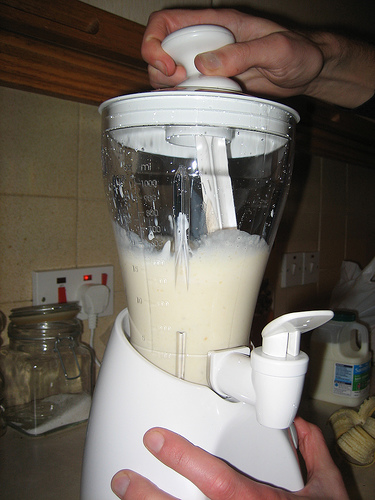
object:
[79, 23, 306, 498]
blender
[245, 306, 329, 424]
spout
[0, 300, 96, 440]
canister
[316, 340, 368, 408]
milk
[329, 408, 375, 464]
banana peel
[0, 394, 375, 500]
counter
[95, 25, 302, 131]
top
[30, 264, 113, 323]
wall outlet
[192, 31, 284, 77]
fingers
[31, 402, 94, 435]
powder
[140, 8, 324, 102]
hand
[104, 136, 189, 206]
splatters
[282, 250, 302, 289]
light switches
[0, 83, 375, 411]
wall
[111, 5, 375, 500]
person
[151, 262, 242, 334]
snack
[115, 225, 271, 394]
drink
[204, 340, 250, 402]
spigot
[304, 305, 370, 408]
bottle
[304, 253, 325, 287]
switches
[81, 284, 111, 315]
plug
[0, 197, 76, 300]
tile